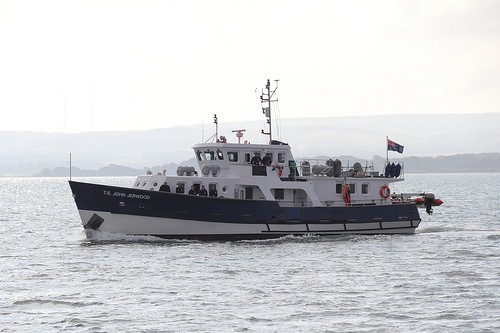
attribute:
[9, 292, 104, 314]
wave — small 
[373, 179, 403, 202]
device — red 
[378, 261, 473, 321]
waves — white , blue 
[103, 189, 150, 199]
letters — white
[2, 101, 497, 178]
mountain slopes — distant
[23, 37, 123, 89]
clouds — white 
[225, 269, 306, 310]
wave — white , blue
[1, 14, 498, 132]
clouds — white 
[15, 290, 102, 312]
wave — blue, white 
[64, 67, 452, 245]
boat — white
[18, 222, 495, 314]
ocean — blue , white 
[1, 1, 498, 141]
sky — clear 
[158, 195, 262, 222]
stripe — blue 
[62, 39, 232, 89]
cloud — white 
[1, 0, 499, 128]
sky — blue 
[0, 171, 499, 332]
water — dark 